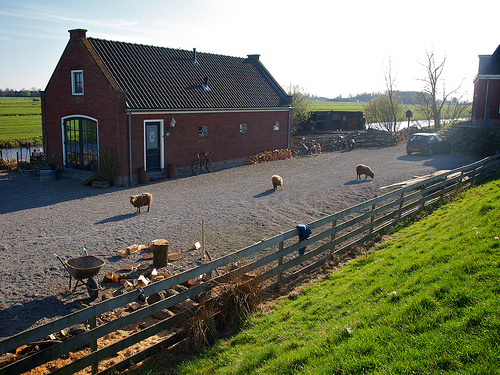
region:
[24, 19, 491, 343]
a farm in the country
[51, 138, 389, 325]
this baryard has animals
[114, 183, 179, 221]
this is a sheep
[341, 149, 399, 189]
this is a pig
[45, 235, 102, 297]
a wheel barrow on the farm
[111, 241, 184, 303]
chopped logs on the ground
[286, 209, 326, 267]
a jacket on a fence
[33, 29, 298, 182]
a modern barn house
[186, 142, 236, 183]
a bicycle next to the wall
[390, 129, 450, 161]
a car on the property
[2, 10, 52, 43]
white clouds in blue sky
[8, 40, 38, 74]
white clouds in blue sky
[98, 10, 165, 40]
white clouds in blue sky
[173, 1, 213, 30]
white clouds in blue sky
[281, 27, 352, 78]
white clouds in blue sky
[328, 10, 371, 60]
white clouds in blue sky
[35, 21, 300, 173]
red barn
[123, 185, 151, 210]
brown sheep on road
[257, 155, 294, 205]
brown sheep on road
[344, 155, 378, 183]
brown sheep on road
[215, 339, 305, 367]
Small part of green grass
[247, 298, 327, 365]
Small part of green grass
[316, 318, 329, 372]
Small part of green grass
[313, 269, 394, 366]
Small part of green grass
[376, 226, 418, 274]
Small part of green grass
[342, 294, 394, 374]
Small part of green grass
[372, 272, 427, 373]
Small part of green grass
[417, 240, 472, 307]
Small part of green grass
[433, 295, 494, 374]
Small part of green grass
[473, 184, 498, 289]
Small part of green grass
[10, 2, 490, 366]
animals in a farm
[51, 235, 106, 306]
a wheelbarrow in the farm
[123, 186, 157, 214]
a sheep color brown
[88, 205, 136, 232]
shadow cast on the ground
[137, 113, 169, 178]
a door on side of house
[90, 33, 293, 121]
roof of house is black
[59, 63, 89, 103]
a small front window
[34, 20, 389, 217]
sheeps on front a house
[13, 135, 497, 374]
a fence of wood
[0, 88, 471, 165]
a creek behind a house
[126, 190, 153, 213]
sheep near the barn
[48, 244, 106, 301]
wheelbarrow on the gravel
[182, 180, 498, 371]
grass on the hillside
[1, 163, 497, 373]
wood fence along the grassy hillside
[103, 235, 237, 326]
chopped wood near the wheelbarrow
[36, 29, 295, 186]
a red brick barn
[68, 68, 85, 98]
window in the brick barn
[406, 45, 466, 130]
bare brown tree by the river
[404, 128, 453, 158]
car parked in the gravel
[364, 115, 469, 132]
river running behind the barn